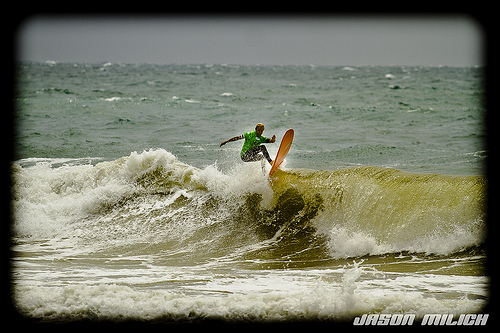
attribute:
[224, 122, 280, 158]
man — surfing, white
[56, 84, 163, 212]
water — green, white, clear, wavy, splashing, deep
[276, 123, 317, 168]
board — orange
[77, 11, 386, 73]
sky — gray